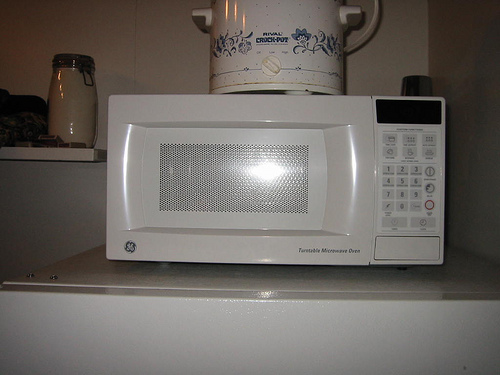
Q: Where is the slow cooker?
A: On top of the microwave.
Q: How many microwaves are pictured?
A: 1.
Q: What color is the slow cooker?
A: White and blue.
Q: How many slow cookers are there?
A: 1.